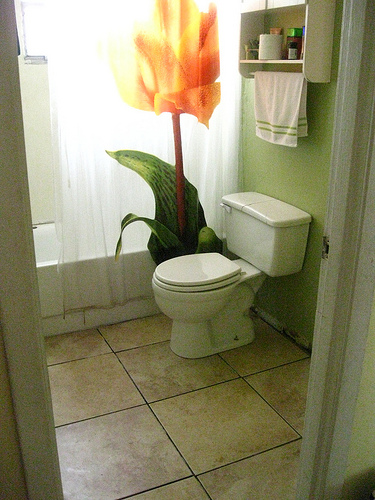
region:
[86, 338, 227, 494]
the floor is tiled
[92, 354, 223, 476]
the floor is tiled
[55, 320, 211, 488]
the floor is tiled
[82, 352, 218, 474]
the floor is tiled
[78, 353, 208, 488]
the floor is tiled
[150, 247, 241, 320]
toilet lid is down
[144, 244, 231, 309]
toilet lid is down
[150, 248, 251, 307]
toilet lid is down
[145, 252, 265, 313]
toilet lid is down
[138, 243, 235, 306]
toilet lid is down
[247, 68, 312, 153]
the towel is white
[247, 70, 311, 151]
towel has green stripes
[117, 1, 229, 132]
the flower is yellow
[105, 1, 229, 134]
the flower is big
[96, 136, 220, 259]
the leaves of the flower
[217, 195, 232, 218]
a handle of a tank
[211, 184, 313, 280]
a tank behind a toilet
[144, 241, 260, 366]
the toilet is closed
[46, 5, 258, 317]
a white curtain in front a shower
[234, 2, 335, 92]
a shelf color white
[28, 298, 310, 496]
large stained tiles on bathroom floor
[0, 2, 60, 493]
dark speckles on door molding and wall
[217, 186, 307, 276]
crack across width of toilet tank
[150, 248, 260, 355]
lid closed over seat and seat closed over bowl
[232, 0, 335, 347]
white rack attached to green wall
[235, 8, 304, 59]
roll of toilet paper and containers on shelf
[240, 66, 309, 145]
white towel with green stripes hanging from rod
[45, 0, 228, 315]
large yellow flower, stem and leaf on shower curtain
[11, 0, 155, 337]
light coming through window over bathtub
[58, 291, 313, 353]
dirt on hem of curtain and floor edge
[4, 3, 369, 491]
Bathroom with tiled floor.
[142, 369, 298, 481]
Tiles are square shaped.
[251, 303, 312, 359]
Bottom of the wall is damaged.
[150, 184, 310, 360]
White porcelain toilet.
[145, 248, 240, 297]
Toilet seat cover is down.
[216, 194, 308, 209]
Top of the water tank is cracked.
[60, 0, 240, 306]
Bathroom curtain with a giant tulip design.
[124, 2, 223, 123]
Tulip flower is orange.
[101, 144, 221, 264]
Large tulip leaves are green.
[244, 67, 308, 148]
White with green stripes towel above the toilet water tank.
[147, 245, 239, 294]
toilet lid is down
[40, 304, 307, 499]
tile on the floor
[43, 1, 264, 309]
flower on the shower curtain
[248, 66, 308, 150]
towel hanging on a rod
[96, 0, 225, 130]
orange petals around the flower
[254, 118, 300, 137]
two green lines at the bottom of the tile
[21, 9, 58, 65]
window on the shower wall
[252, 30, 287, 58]
a roll of toilet paper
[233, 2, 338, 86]
white shelf attached to the wall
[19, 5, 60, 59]
light shining through the window